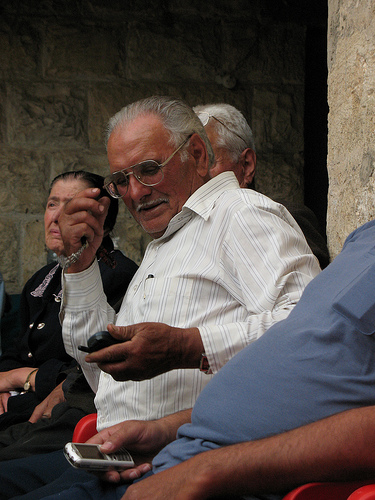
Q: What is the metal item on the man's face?
A: Glasses.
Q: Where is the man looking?
A: At the phone.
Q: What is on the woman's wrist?
A: A watch.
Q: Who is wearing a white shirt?
A: The man with the mustache.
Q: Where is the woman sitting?
A: Next to the men.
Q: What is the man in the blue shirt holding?
A: A cell phone.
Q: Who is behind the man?
A: Woman in black outfit.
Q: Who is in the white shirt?
A: Man wearing glasses.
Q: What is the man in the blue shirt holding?
A: Silver cell phone.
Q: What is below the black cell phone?
A: Someone holding silver phone.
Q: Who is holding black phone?
A: Man in long sleeve white shirt.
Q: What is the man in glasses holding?
A: A black cell phone.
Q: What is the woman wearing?
A: Black long sleeve shirt.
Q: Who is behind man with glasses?
A: Man with glasses on his head.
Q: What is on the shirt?
A: Stripes.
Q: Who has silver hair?
A: The man.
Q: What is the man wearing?
A: A blue shirt.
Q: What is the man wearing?
A: Glasses.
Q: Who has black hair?
A: The woman.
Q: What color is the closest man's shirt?
A: Blue.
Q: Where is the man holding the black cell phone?
A: In the center.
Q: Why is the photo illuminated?
A: Sunlight.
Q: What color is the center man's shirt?
A: White.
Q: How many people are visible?
A: 4.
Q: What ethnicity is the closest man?
A: White.